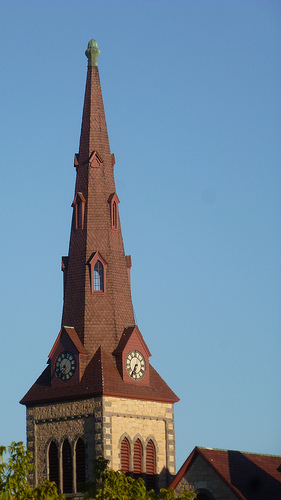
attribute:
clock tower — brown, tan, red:
[16, 34, 185, 497]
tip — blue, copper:
[79, 38, 105, 72]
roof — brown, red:
[16, 61, 185, 409]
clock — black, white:
[121, 350, 149, 381]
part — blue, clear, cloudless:
[2, 4, 275, 480]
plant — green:
[4, 440, 62, 496]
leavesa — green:
[92, 453, 194, 498]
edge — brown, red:
[162, 444, 276, 493]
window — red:
[117, 434, 133, 481]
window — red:
[133, 434, 147, 486]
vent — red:
[145, 435, 158, 490]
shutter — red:
[60, 439, 73, 486]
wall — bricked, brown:
[103, 397, 176, 498]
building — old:
[153, 438, 277, 498]